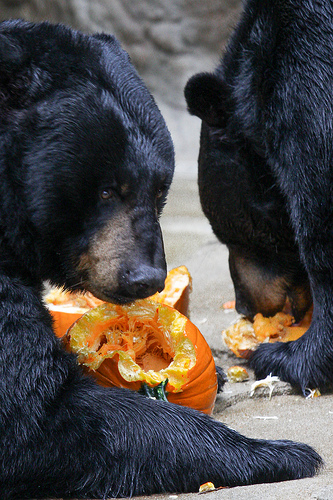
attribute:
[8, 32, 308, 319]
heads — bear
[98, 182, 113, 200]
eye — one, bear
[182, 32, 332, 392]
bear — one, black, large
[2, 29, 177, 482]
bear — one, black, large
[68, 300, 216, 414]
pumpkin — eaten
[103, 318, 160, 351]
stuff — stringy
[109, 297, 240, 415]
pumpkin — stemmed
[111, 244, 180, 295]
nose — black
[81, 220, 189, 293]
snout — tan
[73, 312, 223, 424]
pumkin — orange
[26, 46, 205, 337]
bear — black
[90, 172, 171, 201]
eyes — open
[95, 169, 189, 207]
eyes — brown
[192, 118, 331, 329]
bear — eating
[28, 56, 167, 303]
bear — looking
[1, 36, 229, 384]
bear — wet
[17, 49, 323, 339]
bears — black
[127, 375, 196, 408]
stem — green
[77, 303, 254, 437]
pumpkin — orange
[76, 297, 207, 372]
pumpkin — smashed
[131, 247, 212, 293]
nose — shiny, black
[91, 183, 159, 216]
eye — small, round, shiny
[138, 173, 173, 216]
eye — small, round, shiny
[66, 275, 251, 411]
pumpkin — broken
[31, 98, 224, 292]
face — black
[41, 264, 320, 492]
pumpkin — destroyed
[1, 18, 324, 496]
bear — black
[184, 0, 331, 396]
bear — black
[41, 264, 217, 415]
pumpkin — smashed, half-eaten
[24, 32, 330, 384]
bears — enjoying, eating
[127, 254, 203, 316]
nose — black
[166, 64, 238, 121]
ear — round, nubby